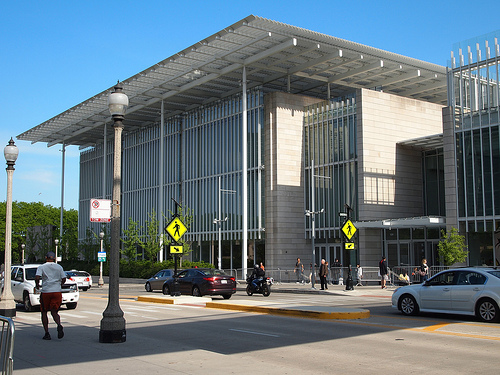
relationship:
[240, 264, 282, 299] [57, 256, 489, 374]
motorcycle on road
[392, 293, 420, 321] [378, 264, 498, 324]
tire on car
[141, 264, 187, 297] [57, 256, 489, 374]
car on road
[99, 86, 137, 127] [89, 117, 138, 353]
light on a pole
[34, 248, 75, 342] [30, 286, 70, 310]
man wearing shorts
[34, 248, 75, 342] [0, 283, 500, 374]
man on road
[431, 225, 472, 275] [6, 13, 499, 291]
tree by building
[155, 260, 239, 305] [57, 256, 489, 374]
car on road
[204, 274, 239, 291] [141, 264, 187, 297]
tail light on car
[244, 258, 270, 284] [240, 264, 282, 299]
man on motorcycle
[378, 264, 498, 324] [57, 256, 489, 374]
car on road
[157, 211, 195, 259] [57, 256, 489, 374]
crosswalk sign over road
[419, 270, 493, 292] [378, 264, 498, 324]
windows are on car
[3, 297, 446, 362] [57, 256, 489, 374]
shadow on road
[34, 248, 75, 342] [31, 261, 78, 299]
man wearing a shirt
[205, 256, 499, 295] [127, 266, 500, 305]
fence on sidewalk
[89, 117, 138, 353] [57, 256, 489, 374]
pole by road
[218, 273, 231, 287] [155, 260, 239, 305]
license plate on car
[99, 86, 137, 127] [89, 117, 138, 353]
light on pole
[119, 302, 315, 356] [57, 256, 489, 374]
line on road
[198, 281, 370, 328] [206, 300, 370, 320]
curb on curb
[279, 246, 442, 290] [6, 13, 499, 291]
people are in front of building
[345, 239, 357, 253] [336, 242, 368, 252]
arrow on sign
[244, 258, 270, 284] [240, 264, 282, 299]
man on a motorcycle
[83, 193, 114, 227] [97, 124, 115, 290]
sign on a pole